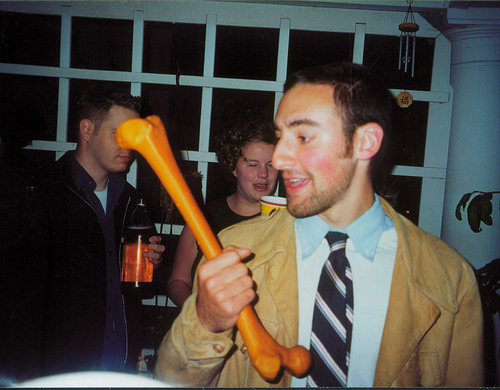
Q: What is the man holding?
A: A bone.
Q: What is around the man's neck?
A: Tie.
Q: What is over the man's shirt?
A: Jacket.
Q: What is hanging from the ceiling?
A: Wind chime.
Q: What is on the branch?
A: Green leaves.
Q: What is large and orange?
A: The bone.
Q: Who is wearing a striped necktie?
A: The man.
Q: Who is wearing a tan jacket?
A: The man.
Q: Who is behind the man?
A: A woman.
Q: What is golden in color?
A: The femur bone.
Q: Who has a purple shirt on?
A: The man.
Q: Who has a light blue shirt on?
A: The man.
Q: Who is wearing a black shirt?
A: The woman.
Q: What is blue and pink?
A: A tie.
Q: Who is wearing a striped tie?
A: A man.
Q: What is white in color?
A: A column.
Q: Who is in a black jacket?
A: A man.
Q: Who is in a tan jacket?
A: A man.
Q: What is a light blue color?
A: A shirt.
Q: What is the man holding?
A: A bone.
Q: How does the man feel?
A: Happy.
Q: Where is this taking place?
A: At a party.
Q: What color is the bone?
A: Orange.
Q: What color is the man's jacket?
A: Beige.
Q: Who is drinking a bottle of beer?
A: The man in the background.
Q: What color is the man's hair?
A: Brown.